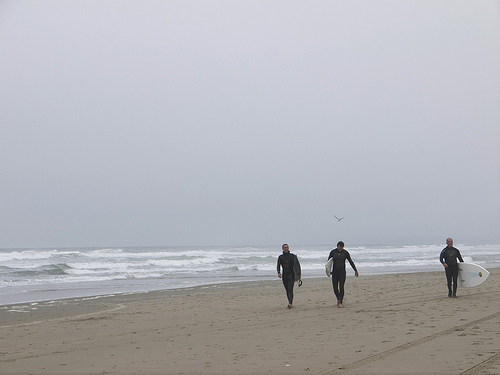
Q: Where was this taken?
A: Beach.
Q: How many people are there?
A: 3.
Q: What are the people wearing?
A: Wetsuits.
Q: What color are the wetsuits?
A: Black.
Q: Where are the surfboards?
A: In the people's hands.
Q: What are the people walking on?
A: Sand.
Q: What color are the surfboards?
A: White.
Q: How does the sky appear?
A: Overcast.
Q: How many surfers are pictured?
A: Three.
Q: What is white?
A: Waves.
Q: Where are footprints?
A: On the sand.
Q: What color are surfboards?
A: White.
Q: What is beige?
A: The sand.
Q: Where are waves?
A: In the ocean.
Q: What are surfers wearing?
A: Wetsuits.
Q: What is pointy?
A: Surfboards.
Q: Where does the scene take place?
A: At the beach.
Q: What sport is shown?
A: Surfing.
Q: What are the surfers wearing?
A: Wetsuits.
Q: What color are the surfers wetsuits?
A: Black.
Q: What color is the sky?
A: Blue grey.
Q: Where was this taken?
A: Beach.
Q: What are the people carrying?
A: Surfboards.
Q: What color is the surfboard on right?
A: White.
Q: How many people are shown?
A: Three.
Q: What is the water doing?
A: Crashing into the beach.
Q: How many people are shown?
A: Three.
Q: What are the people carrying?
A: Surfboards.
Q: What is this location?
A: A beach.